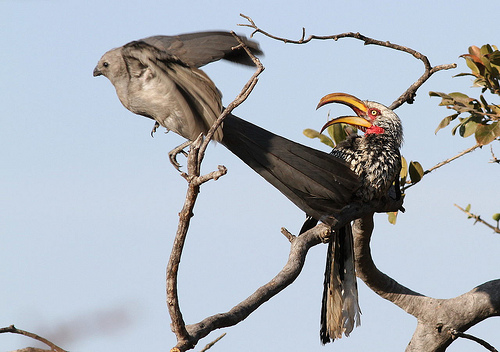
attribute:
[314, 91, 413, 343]
bird — white, red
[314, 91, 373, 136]
beak — yellow, large, curved, orange, pointed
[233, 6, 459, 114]
branch — part, bare, skinny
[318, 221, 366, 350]
tail — wing, gray, black, long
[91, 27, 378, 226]
bird — gray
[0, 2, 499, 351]
sky — blue, part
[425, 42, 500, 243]
leaves — green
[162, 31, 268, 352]
branch — think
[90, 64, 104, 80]
beak — gray, pointed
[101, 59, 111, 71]
eyeball — black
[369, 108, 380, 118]
eye — white, small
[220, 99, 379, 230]
tail — long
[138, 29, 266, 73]
wing — grey